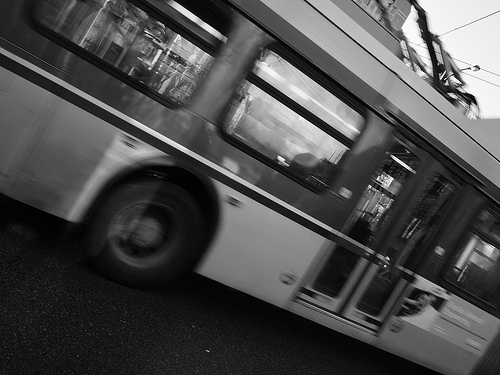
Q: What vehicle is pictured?
A: Bus.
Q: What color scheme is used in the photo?
A: Black and white.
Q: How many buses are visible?
A: 1.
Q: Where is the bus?
A: On the road.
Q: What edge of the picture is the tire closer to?
A: Left.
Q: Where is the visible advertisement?
A: On the bus.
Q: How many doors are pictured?
A: 2.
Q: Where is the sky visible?
A: Top right corner.